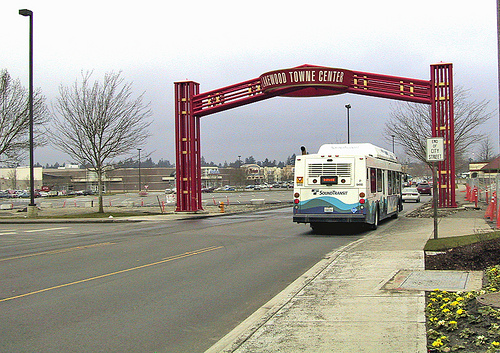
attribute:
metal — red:
[171, 77, 206, 214]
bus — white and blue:
[218, 128, 423, 262]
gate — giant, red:
[168, 60, 468, 219]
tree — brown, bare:
[46, 75, 163, 213]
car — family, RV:
[287, 123, 401, 208]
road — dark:
[1, 216, 331, 352]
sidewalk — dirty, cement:
[206, 207, 489, 351]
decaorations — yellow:
[176, 86, 190, 201]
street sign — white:
[428, 137, 447, 162]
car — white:
[402, 187, 419, 200]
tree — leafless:
[49, 65, 160, 221]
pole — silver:
[425, 171, 444, 240]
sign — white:
[423, 136, 446, 167]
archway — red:
[141, 49, 482, 218]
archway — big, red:
[174, 57, 458, 217]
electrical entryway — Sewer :
[396, 269, 468, 288]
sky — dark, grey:
[12, 13, 470, 170]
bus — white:
[285, 100, 428, 263]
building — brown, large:
[48, 74, 285, 276]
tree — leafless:
[48, 78, 135, 230]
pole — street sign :
[431, 165, 438, 240]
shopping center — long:
[1, 165, 292, 193]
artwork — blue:
[294, 191, 374, 220]